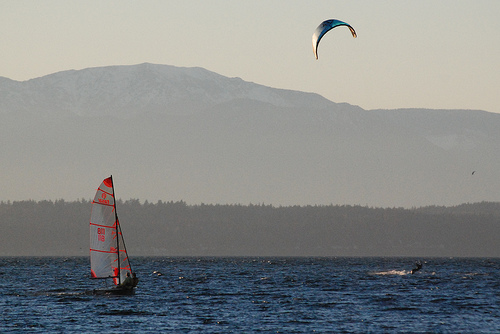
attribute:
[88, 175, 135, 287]
sail — orange, red, colorful, white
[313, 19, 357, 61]
kite — real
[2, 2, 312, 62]
sky — blue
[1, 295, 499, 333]
water — rippled, blue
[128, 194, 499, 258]
trees — real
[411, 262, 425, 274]
man — parasailing